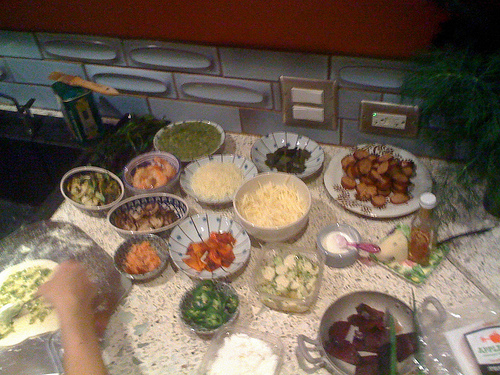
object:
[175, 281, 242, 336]
dish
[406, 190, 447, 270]
jar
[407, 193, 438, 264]
condiment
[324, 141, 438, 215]
dish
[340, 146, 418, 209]
sausage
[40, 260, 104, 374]
hand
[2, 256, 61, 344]
food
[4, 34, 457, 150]
panel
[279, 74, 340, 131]
switches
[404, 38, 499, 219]
houseplant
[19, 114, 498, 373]
table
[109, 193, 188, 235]
bowl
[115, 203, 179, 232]
mushrooms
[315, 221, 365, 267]
dish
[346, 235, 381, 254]
spoon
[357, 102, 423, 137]
outlet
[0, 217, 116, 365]
plate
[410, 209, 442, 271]
bottle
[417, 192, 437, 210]
cap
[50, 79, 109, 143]
canister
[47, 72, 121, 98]
brush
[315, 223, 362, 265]
bowl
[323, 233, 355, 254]
cream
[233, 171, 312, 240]
bowl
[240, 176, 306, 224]
cheese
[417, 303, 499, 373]
packaging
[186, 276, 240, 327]
jalapeno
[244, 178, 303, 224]
white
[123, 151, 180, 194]
bowl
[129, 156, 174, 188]
shrimp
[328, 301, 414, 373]
food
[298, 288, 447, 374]
bowl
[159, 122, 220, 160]
sauce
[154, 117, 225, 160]
bowl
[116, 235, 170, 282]
bowl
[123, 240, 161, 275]
food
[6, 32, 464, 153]
tiles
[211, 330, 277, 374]
substance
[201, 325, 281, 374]
container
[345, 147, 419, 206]
pieces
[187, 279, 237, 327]
green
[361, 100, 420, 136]
plates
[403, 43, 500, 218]
bushy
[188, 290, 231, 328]
slices